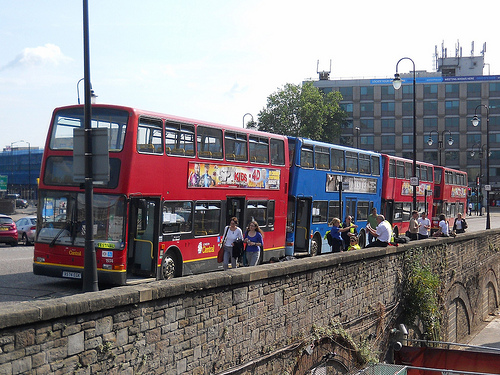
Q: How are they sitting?
A: On edge.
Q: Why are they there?
A: Touring.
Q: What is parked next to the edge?
A: Autobuses.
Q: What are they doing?
A: Relaxing.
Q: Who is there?
A: Tourists.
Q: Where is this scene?
A: City street.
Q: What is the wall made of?
A: Stone.